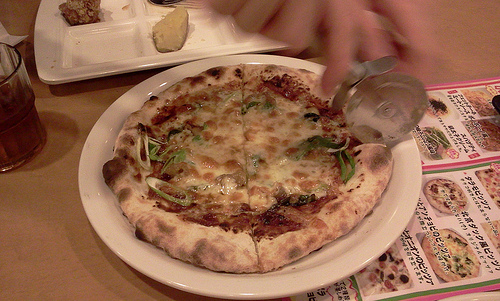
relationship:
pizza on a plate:
[102, 62, 394, 273] [77, 53, 425, 300]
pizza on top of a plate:
[102, 62, 394, 273] [77, 53, 425, 300]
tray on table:
[33, 0, 312, 84] [1, 0, 499, 300]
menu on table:
[273, 74, 499, 300] [1, 0, 499, 300]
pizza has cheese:
[102, 62, 394, 273] [146, 79, 351, 236]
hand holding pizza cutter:
[208, 1, 437, 100] [310, 38, 428, 147]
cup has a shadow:
[0, 41, 47, 174] [11, 110, 78, 170]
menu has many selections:
[273, 74, 499, 300] [358, 166, 499, 299]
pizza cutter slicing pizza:
[310, 38, 428, 147] [102, 62, 394, 273]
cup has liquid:
[0, 41, 47, 174] [0, 73, 45, 168]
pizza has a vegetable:
[102, 62, 394, 273] [338, 148, 356, 183]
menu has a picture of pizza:
[273, 74, 499, 300] [424, 177, 468, 216]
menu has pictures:
[273, 74, 499, 300] [410, 80, 499, 165]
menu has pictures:
[273, 74, 499, 300] [417, 166, 499, 284]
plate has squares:
[33, 0, 312, 84] [64, 0, 142, 67]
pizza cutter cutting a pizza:
[310, 38, 428, 147] [102, 62, 394, 273]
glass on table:
[1, 37, 51, 177] [1, 0, 499, 300]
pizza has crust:
[102, 62, 394, 273] [170, 228, 317, 282]